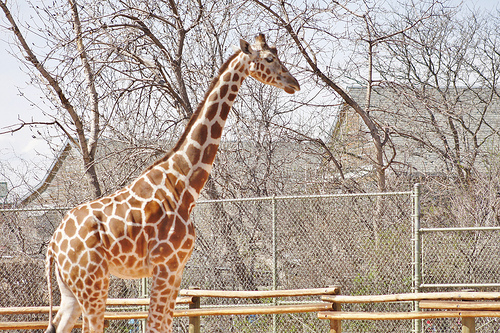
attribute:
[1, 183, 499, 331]
fence — gray, metal, brown, wood, wooden, chain link, silver, wires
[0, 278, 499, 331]
bleachers — brown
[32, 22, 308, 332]
giraffe — large, standing, looking, orange, cream, young adult, brown, white, spotted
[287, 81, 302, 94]
mouth — open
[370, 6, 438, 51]
branches — bare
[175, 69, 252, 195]
neck — long, spotted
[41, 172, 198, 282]
body — spotted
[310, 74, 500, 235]
house — background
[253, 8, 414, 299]
trees — leafless, bare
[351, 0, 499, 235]
trees — leafless, bare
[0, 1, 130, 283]
trees — leafless, bare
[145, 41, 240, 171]
hair — mohawk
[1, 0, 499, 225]
sky — clear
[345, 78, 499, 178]
roof — light green